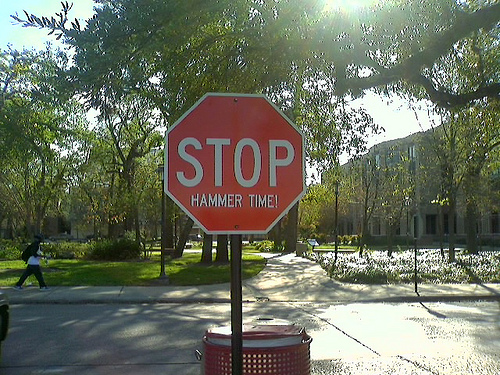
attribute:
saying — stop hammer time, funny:
[172, 126, 302, 218]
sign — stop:
[150, 77, 330, 247]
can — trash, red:
[173, 300, 334, 372]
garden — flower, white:
[333, 233, 473, 296]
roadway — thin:
[6, 291, 495, 361]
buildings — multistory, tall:
[295, 104, 475, 271]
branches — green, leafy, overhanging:
[4, 0, 491, 161]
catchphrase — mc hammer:
[168, 126, 308, 231]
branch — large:
[9, 15, 170, 94]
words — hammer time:
[187, 192, 279, 211]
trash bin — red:
[200, 316, 314, 373]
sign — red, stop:
[157, 83, 311, 243]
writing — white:
[175, 129, 295, 211]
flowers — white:
[317, 244, 497, 285]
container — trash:
[192, 312, 320, 372]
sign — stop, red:
[160, 91, 310, 236]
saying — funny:
[187, 188, 279, 214]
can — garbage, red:
[197, 307, 317, 373]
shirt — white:
[17, 247, 50, 272]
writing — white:
[171, 133, 298, 192]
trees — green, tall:
[2, 43, 91, 247]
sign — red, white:
[155, 69, 344, 369]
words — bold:
[165, 72, 337, 254]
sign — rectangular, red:
[153, 53, 405, 298]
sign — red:
[147, 53, 341, 369]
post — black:
[170, 185, 300, 354]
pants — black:
[15, 260, 50, 326]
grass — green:
[39, 213, 194, 293]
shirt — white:
[18, 211, 54, 276]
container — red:
[182, 303, 293, 369]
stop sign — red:
[151, 91, 314, 243]